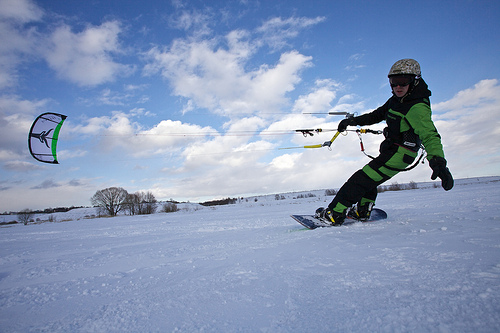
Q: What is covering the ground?
A: Snow.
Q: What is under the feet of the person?
A: Snowboard.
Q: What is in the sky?
A: Clouds.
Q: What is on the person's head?
A: Helmet.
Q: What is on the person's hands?
A: Gloves.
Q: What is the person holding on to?
A: A para-sail.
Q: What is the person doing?
A: Snowboarding.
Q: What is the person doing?
A: A snowsuit.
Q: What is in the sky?
A: Clouds.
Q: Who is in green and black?
A: The snowboarder.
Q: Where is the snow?
A: On the ground.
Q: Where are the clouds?
A: In the sky.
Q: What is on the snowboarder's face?
A: Goggles.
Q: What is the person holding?
A: A harness and rope.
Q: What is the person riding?
A: A snowboard.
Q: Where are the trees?
A: Lining the field.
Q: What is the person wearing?
A: A green and black snowsuit.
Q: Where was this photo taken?
A: Maine.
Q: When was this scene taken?
A: Yesterday.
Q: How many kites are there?
A: 1.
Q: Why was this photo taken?
A: For a magazine.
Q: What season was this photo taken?
A: Winter.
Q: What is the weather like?
A: Cool.